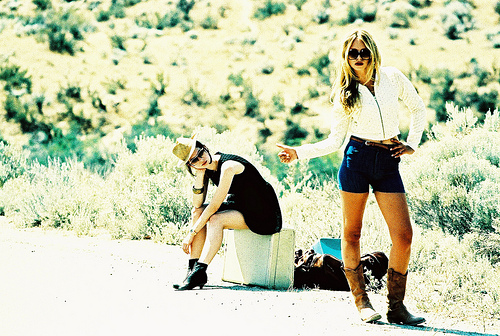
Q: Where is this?
A: This is at the road.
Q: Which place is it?
A: It is a road.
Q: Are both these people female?
A: Yes, all the people are female.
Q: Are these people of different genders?
A: No, all the people are female.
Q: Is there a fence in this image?
A: No, there are no fences.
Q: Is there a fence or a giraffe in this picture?
A: No, there are no fences or giraffes.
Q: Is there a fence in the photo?
A: No, there are no fences.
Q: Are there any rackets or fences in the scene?
A: No, there are no fences or rackets.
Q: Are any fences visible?
A: No, there are no fences.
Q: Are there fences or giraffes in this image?
A: No, there are no fences or giraffes.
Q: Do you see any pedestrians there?
A: No, there are no pedestrians.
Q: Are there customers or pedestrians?
A: No, there are no pedestrians or customers.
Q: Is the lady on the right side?
A: Yes, the lady is on the right of the image.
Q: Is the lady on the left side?
A: No, the lady is on the right of the image.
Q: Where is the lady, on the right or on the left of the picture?
A: The lady is on the right of the image.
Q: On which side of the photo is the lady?
A: The lady is on the right of the image.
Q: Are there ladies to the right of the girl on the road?
A: Yes, there is a lady to the right of the girl.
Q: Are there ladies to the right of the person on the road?
A: Yes, there is a lady to the right of the girl.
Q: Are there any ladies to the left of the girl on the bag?
A: No, the lady is to the right of the girl.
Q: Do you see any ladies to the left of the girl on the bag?
A: No, the lady is to the right of the girl.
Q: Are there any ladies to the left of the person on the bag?
A: No, the lady is to the right of the girl.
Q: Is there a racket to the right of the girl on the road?
A: No, there is a lady to the right of the girl.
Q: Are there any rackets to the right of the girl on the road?
A: No, there is a lady to the right of the girl.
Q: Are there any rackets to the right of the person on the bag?
A: No, there is a lady to the right of the girl.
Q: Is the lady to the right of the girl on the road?
A: Yes, the lady is to the right of the girl.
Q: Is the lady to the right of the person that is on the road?
A: Yes, the lady is to the right of the girl.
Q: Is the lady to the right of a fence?
A: No, the lady is to the right of the girl.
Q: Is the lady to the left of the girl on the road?
A: No, the lady is to the right of the girl.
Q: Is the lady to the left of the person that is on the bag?
A: No, the lady is to the right of the girl.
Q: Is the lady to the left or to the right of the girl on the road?
A: The lady is to the right of the girl.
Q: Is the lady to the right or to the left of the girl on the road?
A: The lady is to the right of the girl.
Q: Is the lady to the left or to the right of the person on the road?
A: The lady is to the right of the girl.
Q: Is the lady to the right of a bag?
A: Yes, the lady is to the right of a bag.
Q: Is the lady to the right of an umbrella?
A: No, the lady is to the right of a bag.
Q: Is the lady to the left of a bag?
A: No, the lady is to the right of a bag.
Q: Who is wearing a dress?
A: The lady is wearing a dress.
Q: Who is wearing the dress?
A: The lady is wearing a dress.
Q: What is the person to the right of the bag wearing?
A: The lady is wearing a dress.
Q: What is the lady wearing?
A: The lady is wearing a dress.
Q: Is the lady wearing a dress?
A: Yes, the lady is wearing a dress.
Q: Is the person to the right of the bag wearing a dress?
A: Yes, the lady is wearing a dress.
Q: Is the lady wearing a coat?
A: No, the lady is wearing a dress.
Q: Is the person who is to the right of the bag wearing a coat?
A: No, the lady is wearing a dress.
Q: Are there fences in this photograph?
A: No, there are no fences.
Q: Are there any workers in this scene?
A: No, there are no workers.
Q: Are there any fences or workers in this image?
A: No, there are no workers or fences.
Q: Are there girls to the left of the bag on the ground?
A: Yes, there is a girl to the left of the bag.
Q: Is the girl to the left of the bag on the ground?
A: Yes, the girl is to the left of the bag.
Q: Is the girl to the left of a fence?
A: No, the girl is to the left of the bag.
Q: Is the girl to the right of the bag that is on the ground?
A: No, the girl is to the left of the bag.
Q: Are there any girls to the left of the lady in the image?
A: Yes, there is a girl to the left of the lady.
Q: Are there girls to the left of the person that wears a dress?
A: Yes, there is a girl to the left of the lady.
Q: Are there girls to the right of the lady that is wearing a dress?
A: No, the girl is to the left of the lady.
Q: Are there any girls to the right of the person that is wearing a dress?
A: No, the girl is to the left of the lady.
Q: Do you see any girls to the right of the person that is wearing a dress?
A: No, the girl is to the left of the lady.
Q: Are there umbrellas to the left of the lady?
A: No, there is a girl to the left of the lady.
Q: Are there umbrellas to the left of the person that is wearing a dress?
A: No, there is a girl to the left of the lady.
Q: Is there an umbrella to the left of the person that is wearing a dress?
A: No, there is a girl to the left of the lady.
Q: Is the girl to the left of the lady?
A: Yes, the girl is to the left of the lady.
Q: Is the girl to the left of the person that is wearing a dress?
A: Yes, the girl is to the left of the lady.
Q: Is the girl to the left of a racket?
A: No, the girl is to the left of the lady.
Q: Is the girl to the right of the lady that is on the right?
A: No, the girl is to the left of the lady.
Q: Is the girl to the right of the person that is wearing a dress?
A: No, the girl is to the left of the lady.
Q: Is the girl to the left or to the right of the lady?
A: The girl is to the left of the lady.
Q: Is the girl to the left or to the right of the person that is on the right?
A: The girl is to the left of the lady.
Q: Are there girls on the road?
A: Yes, there is a girl on the road.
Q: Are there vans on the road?
A: No, there is a girl on the road.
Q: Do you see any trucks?
A: No, there are no trucks.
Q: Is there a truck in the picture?
A: No, there are no trucks.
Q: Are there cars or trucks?
A: No, there are no trucks or cars.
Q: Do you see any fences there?
A: No, there are no fences.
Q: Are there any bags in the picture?
A: Yes, there is a bag.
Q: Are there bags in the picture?
A: Yes, there is a bag.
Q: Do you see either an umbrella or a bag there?
A: Yes, there is a bag.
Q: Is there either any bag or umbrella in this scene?
A: Yes, there is a bag.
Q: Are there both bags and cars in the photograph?
A: No, there is a bag but no cars.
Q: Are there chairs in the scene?
A: No, there are no chairs.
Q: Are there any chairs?
A: No, there are no chairs.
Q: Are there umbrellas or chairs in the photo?
A: No, there are no chairs or umbrellas.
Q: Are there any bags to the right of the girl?
A: Yes, there is a bag to the right of the girl.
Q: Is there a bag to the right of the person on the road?
A: Yes, there is a bag to the right of the girl.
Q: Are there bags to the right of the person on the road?
A: Yes, there is a bag to the right of the girl.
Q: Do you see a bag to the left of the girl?
A: No, the bag is to the right of the girl.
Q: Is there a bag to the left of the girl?
A: No, the bag is to the right of the girl.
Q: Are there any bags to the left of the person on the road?
A: No, the bag is to the right of the girl.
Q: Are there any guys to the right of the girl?
A: No, there is a bag to the right of the girl.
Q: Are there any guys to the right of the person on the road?
A: No, there is a bag to the right of the girl.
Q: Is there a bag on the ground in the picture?
A: Yes, there is a bag on the ground.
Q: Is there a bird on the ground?
A: No, there is a bag on the ground.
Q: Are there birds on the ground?
A: No, there is a bag on the ground.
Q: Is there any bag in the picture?
A: Yes, there is a bag.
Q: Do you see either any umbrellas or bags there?
A: Yes, there is a bag.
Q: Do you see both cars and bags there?
A: No, there is a bag but no cars.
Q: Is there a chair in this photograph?
A: No, there are no chairs.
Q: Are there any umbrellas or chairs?
A: No, there are no chairs or umbrellas.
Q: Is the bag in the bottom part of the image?
A: Yes, the bag is in the bottom of the image.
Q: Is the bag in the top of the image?
A: No, the bag is in the bottom of the image.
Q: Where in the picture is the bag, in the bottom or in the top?
A: The bag is in the bottom of the image.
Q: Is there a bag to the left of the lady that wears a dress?
A: Yes, there is a bag to the left of the lady.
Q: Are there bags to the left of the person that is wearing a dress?
A: Yes, there is a bag to the left of the lady.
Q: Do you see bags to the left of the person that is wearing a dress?
A: Yes, there is a bag to the left of the lady.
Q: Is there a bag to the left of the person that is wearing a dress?
A: Yes, there is a bag to the left of the lady.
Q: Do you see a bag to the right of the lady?
A: No, the bag is to the left of the lady.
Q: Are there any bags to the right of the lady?
A: No, the bag is to the left of the lady.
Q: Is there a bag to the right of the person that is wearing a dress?
A: No, the bag is to the left of the lady.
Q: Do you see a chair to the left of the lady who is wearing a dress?
A: No, there is a bag to the left of the lady.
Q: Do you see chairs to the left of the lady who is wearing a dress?
A: No, there is a bag to the left of the lady.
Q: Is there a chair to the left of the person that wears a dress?
A: No, there is a bag to the left of the lady.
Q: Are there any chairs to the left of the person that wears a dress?
A: No, there is a bag to the left of the lady.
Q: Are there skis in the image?
A: No, there are no skis.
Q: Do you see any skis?
A: No, there are no skis.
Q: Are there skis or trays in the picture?
A: No, there are no skis or trays.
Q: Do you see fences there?
A: No, there are no fences.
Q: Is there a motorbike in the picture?
A: No, there are no motorcycles.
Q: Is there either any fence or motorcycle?
A: No, there are no motorcycles or fences.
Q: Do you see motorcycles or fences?
A: No, there are no motorcycles or fences.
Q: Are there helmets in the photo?
A: No, there are no helmets.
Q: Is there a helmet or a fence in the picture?
A: No, there are no helmets or fences.